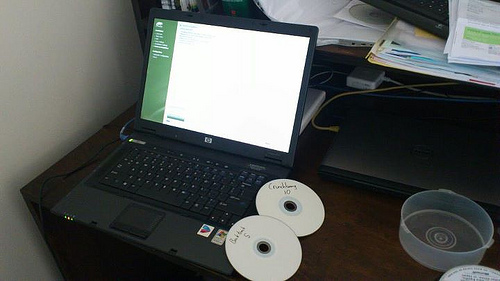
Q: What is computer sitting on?
A: A desk.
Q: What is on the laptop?
A: A white and green screen.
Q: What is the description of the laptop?
A: Black.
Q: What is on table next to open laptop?
A: A closed laptop.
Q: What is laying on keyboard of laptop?
A: White disc.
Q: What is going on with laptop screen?
A: It's on.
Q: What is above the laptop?
A: A stack of papers.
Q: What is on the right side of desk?
A: A disc cover.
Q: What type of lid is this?
A: Plastic.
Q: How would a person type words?
A: Keyboard.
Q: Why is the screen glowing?
A: Laptop is on.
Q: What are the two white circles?
A: Compact discs.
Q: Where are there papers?
A: Rear shelf.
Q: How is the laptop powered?
A: Electric cord.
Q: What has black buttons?
A: Laptop keyboard.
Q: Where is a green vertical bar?
A: Left on laptop screen.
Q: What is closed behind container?
A: Laptop.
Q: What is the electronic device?
A: A laptop.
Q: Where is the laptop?
A: On the desk.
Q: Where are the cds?
A: ON the laptop.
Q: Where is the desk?
A: In an office.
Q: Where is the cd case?
A: On the desk.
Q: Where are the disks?
A: On the keyboard.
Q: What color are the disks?
A: White.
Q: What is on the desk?
A: A computer.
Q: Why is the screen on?
A: The computer is on.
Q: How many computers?
A: 1.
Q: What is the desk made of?
A: Wood.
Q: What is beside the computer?
A: A container.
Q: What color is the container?
A: Clear.